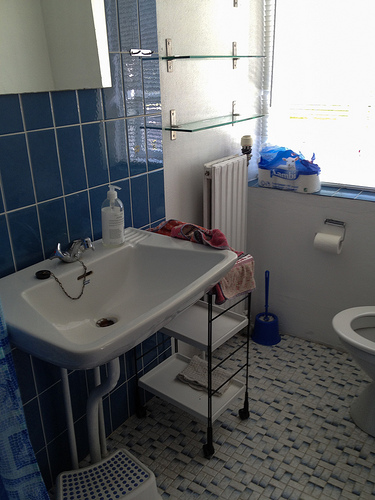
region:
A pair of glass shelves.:
[145, 45, 268, 139]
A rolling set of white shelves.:
[182, 301, 280, 460]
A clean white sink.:
[12, 223, 227, 352]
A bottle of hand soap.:
[82, 181, 137, 252]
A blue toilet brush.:
[252, 270, 290, 349]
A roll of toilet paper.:
[303, 220, 350, 257]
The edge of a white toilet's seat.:
[326, 299, 373, 423]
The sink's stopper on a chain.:
[26, 262, 111, 303]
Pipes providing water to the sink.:
[57, 375, 114, 452]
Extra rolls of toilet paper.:
[250, 143, 334, 198]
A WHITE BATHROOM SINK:
[0, 220, 240, 373]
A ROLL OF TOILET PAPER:
[304, 225, 350, 259]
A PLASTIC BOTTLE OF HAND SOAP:
[95, 180, 135, 251]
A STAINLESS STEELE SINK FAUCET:
[50, 233, 100, 265]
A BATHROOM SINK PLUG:
[32, 261, 96, 301]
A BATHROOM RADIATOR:
[193, 145, 253, 256]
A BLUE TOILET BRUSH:
[251, 262, 287, 348]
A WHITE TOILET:
[318, 297, 373, 442]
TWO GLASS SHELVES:
[133, 30, 277, 143]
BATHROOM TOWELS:
[141, 213, 258, 307]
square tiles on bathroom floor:
[233, 451, 280, 478]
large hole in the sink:
[87, 303, 122, 339]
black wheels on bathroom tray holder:
[234, 391, 267, 419]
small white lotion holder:
[97, 179, 138, 248]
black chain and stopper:
[27, 260, 83, 302]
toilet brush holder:
[256, 259, 286, 360]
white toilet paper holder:
[306, 215, 364, 260]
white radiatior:
[203, 157, 268, 260]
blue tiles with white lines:
[24, 179, 84, 222]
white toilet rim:
[325, 295, 373, 333]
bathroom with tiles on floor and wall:
[30, 66, 363, 430]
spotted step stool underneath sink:
[50, 439, 162, 491]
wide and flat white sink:
[17, 201, 238, 367]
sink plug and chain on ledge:
[30, 246, 94, 302]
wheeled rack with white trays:
[156, 228, 257, 455]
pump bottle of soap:
[96, 165, 129, 250]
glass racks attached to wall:
[127, 30, 274, 150]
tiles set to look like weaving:
[251, 369, 336, 474]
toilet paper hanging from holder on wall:
[305, 207, 350, 255]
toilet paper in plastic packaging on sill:
[248, 130, 325, 198]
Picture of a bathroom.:
[13, 32, 361, 488]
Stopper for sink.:
[36, 259, 92, 300]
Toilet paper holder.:
[309, 207, 351, 262]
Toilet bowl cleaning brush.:
[249, 259, 282, 349]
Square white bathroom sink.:
[6, 221, 225, 364]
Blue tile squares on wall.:
[17, 101, 137, 177]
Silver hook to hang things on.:
[124, 38, 151, 62]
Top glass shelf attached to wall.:
[155, 19, 263, 70]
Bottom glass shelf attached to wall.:
[150, 91, 257, 137]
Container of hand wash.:
[91, 183, 134, 251]